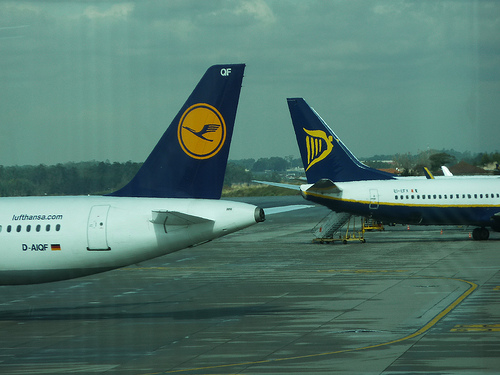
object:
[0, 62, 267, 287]
airplane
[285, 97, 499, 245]
airplane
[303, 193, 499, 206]
stripe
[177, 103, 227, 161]
logo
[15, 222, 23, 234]
window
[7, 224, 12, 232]
window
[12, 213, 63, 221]
lettering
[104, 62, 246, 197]
blue tail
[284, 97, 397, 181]
blue tail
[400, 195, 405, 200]
window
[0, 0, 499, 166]
sky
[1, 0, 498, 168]
clouds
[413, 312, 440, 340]
lines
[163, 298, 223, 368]
ground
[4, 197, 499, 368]
runway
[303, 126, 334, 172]
logo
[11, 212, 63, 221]
lufthansa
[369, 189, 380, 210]
door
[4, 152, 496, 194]
trees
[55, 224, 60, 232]
window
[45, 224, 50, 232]
window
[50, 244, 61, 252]
flag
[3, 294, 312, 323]
shadow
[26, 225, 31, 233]
window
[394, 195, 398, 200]
window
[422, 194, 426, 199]
window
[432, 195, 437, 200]
window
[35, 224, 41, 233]
window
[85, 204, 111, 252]
door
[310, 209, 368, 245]
stair case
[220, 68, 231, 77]
letters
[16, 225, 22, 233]
window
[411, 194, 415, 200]
window